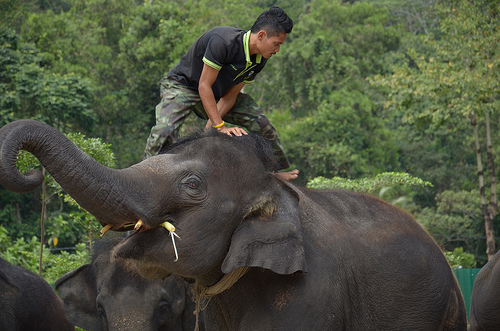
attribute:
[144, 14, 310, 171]
man — barefoot, climbing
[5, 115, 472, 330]
elephant — eating, grey, standing, present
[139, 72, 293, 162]
pants — camouflage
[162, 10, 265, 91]
shirt — black, blue, green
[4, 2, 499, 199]
trees — green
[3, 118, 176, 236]
trunk — airborne, present, large, raised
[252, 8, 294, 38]
hair — black, dark, spikey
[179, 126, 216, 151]
fur — short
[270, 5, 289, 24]
haircut — interesting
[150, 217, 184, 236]
tusks — present, short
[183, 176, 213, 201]
eyes — present, open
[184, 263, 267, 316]
cloth — rope, present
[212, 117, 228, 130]
wristband — yellow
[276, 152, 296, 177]
foot — exposed